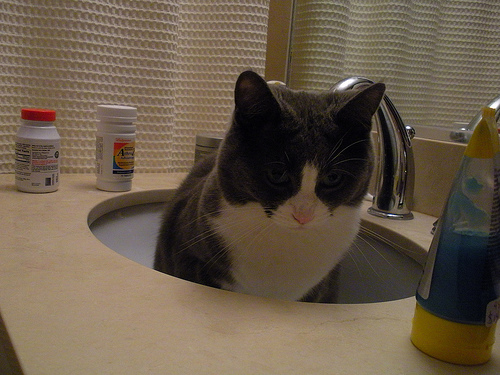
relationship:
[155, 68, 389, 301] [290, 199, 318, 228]
cat has nose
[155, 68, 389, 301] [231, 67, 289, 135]
cat has ear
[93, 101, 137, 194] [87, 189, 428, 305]
bottle on side of sink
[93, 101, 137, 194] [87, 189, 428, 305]
bottle on top of sink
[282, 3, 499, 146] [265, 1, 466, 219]
mirror hanging on wall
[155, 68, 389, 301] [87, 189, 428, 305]
cat sitting in sink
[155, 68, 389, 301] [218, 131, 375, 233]
cat has face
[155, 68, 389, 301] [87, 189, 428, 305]
cat in sink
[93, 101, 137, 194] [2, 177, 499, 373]
bottle on top of counter top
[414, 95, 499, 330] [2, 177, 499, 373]
tube on top of counter top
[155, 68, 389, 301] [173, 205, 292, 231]
cat has whisker